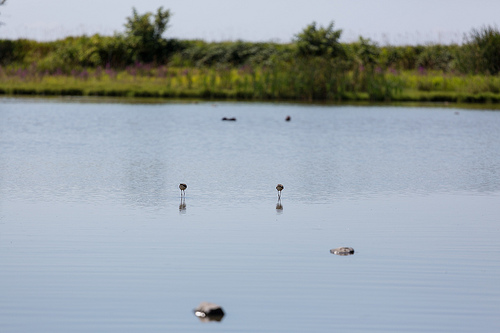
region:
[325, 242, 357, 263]
bird sitting in a still lake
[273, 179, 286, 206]
bird sitting in a still lake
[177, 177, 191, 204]
bird sitting in a still lake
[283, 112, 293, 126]
bird sitting in a still lake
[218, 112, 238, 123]
bird sitting in a still lake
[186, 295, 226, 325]
bird sitting in a still lake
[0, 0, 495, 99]
shore covered with trees and brush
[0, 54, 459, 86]
purple flowers on the bank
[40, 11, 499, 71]
row of bushes on the bank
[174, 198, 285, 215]
reflection of the birds on the water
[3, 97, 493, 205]
ripples in the water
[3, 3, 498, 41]
gray skies above the bushes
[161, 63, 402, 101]
weeds growing along the waterway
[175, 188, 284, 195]
legs of the birds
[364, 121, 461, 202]
Large body of water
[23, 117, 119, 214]
Large body of blue water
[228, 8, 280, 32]
Large body of skies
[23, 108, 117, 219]
Large area of blue water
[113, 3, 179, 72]
Large green tree in background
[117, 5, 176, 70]
Large tree in background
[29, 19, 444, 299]
this is a pond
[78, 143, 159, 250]
the pond is blue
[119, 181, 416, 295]
these are animals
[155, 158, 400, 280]
these are ducks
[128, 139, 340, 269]
the ducks are light gray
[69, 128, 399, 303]
the water is calm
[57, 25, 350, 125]
these plants are green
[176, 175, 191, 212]
buoy in the lake water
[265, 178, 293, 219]
buoy in the lake water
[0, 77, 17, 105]
rocks in the lake water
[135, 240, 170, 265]
a view of riples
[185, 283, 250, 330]
a view of stones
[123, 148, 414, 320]
birds in the water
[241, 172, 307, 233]
bird in the water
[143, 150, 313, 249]
two birds near each other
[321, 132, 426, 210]
ripples in the water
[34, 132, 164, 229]
water next to the birds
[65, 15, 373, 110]
trees near the water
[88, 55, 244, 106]
green grass next to water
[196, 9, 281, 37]
sky above the land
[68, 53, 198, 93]
purple flowers on ground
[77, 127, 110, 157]
calm blue dark water in river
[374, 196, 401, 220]
calm blue dark water in river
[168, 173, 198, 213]
buoy in dark water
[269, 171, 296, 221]
buoy in dark water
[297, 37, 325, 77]
green leaves in brown trees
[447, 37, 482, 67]
green leaves in brown trees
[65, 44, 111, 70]
green leaves in brown trees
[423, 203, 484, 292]
blue water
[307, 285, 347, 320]
water is blue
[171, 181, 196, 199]
a bird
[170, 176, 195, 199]
bird in the water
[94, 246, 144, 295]
water is blue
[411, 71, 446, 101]
the grass is tall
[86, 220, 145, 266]
blue water in the lake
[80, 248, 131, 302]
the lake